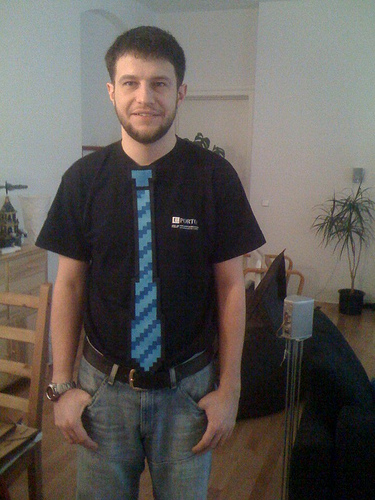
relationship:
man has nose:
[32, 26, 266, 494] [137, 79, 154, 105]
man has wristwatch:
[32, 26, 266, 494] [40, 377, 76, 403]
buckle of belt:
[128, 367, 167, 390] [80, 336, 215, 389]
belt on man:
[80, 336, 215, 389] [32, 26, 266, 494]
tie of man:
[131, 167, 165, 372] [32, 26, 266, 494]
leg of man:
[75, 373, 146, 498] [32, 26, 266, 494]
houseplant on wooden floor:
[307, 172, 373, 318] [1, 297, 372, 497]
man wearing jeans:
[32, 26, 266, 494] [64, 346, 223, 498]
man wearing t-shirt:
[32, 26, 266, 494] [41, 141, 264, 366]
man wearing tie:
[32, 26, 266, 494] [127, 162, 164, 368]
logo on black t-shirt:
[165, 203, 201, 236] [51, 152, 243, 382]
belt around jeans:
[80, 336, 215, 389] [76, 337, 214, 499]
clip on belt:
[126, 368, 147, 390] [80, 336, 215, 389]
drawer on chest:
[6, 255, 49, 293] [1, 241, 51, 387]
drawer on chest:
[7, 286, 43, 320] [1, 241, 51, 387]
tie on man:
[131, 167, 165, 372] [17, 20, 272, 297]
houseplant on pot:
[307, 172, 375, 315] [337, 288, 364, 316]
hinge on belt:
[128, 366, 148, 392] [123, 368, 162, 400]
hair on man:
[104, 26, 187, 90] [41, 45, 264, 360]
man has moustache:
[32, 26, 266, 494] [131, 104, 163, 119]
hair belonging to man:
[104, 26, 187, 90] [32, 26, 266, 494]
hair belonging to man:
[120, 33, 165, 50] [32, 26, 266, 494]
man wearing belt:
[51, 26, 284, 461] [80, 336, 215, 389]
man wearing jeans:
[32, 26, 266, 494] [55, 333, 226, 498]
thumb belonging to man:
[84, 394, 92, 406] [32, 26, 266, 494]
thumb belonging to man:
[193, 394, 207, 411] [32, 26, 266, 494]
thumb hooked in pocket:
[84, 394, 92, 406] [73, 376, 110, 449]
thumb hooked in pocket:
[193, 394, 207, 411] [181, 385, 229, 451]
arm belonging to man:
[212, 159, 247, 394] [32, 26, 266, 494]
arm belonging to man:
[48, 172, 89, 392] [32, 26, 266, 494]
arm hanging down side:
[212, 159, 247, 394] [201, 175, 219, 352]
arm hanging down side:
[48, 172, 89, 392] [81, 188, 103, 354]